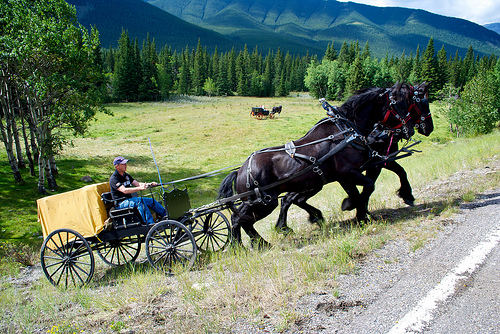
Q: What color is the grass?
A: Green.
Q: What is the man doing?
A: Being hauled by horses.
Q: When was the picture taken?
A: In the day time.